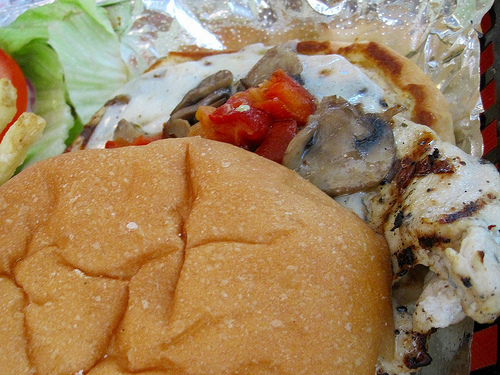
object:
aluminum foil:
[0, 0, 499, 159]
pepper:
[196, 69, 316, 165]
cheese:
[82, 53, 389, 149]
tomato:
[196, 69, 319, 164]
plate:
[0, 0, 500, 375]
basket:
[478, 6, 500, 173]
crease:
[171, 143, 200, 324]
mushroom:
[282, 95, 408, 196]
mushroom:
[164, 70, 232, 138]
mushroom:
[236, 45, 305, 91]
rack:
[482, 31, 498, 161]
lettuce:
[0, 0, 135, 179]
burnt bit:
[397, 154, 455, 187]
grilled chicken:
[366, 114, 500, 375]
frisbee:
[66, 41, 455, 225]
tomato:
[0, 48, 28, 142]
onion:
[25, 78, 36, 112]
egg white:
[84, 40, 497, 373]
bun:
[0, 137, 392, 375]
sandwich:
[0, 0, 500, 375]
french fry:
[0, 111, 46, 183]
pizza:
[0, 135, 393, 375]